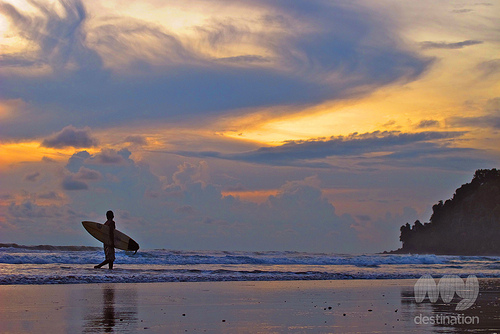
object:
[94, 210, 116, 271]
man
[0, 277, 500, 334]
beach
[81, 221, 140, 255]
surboard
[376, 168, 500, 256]
trees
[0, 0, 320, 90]
clouds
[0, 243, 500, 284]
ocean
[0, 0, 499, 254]
sky